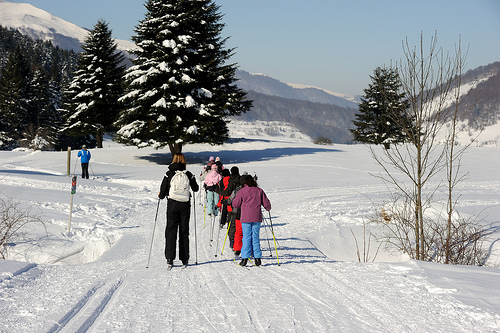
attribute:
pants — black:
[165, 197, 191, 263]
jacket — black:
[156, 165, 197, 201]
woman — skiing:
[159, 154, 199, 264]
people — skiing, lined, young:
[201, 155, 272, 268]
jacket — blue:
[78, 148, 91, 165]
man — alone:
[76, 145, 91, 180]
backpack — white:
[169, 170, 193, 204]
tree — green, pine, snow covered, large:
[349, 66, 424, 149]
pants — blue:
[238, 221, 262, 259]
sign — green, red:
[70, 174, 77, 197]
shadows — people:
[258, 216, 338, 267]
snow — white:
[0, 141, 498, 331]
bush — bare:
[367, 32, 484, 266]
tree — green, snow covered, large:
[112, 1, 254, 155]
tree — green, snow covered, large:
[65, 20, 128, 126]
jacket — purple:
[231, 184, 273, 226]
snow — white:
[2, 2, 365, 106]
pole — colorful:
[65, 146, 73, 179]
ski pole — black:
[145, 197, 162, 271]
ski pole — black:
[192, 192, 199, 267]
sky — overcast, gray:
[15, 1, 499, 105]